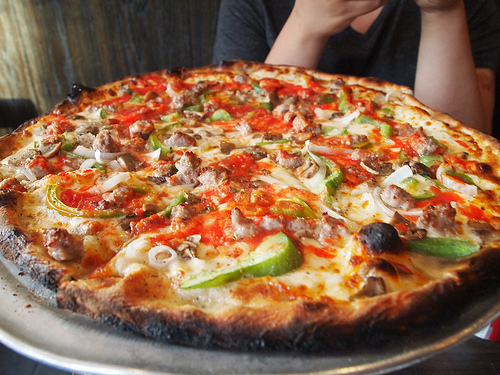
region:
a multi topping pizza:
[1, 59, 498, 349]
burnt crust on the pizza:
[108, 286, 476, 344]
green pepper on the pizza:
[190, 232, 304, 288]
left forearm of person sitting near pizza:
[413, 14, 485, 132]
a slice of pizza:
[56, 151, 462, 337]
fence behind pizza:
[6, 6, 204, 71]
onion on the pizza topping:
[139, 239, 184, 279]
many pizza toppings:
[68, 98, 416, 280]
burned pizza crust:
[2, 225, 499, 349]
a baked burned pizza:
[0, 61, 497, 353]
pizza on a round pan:
[0, 59, 497, 371]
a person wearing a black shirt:
[209, 0, 499, 125]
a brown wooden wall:
[0, 2, 217, 137]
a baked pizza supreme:
[3, 60, 495, 344]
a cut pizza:
[1, 62, 498, 355]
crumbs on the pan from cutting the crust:
[1, 261, 40, 323]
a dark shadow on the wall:
[1, 98, 34, 139]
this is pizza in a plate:
[3, 55, 498, 350]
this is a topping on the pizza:
[190, 222, 326, 282]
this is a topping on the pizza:
[349, 220, 401, 269]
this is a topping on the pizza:
[398, 206, 494, 273]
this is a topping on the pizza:
[41, 170, 143, 236]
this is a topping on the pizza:
[149, 136, 207, 184]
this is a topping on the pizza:
[189, 95, 246, 134]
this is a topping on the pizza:
[284, 139, 346, 203]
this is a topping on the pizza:
[21, 140, 68, 180]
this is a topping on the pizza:
[177, 135, 220, 196]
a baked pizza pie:
[2, 53, 499, 338]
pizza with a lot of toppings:
[12, 48, 499, 370]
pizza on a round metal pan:
[5, 43, 494, 373]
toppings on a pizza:
[85, 91, 269, 247]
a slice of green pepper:
[192, 233, 305, 297]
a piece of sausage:
[90, 128, 120, 155]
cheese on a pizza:
[127, 119, 297, 199]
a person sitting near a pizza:
[205, 31, 497, 126]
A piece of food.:
[348, 222, 390, 257]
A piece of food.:
[396, 232, 478, 260]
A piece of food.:
[378, 187, 422, 215]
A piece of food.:
[317, 155, 344, 200]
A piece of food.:
[251, 132, 294, 147]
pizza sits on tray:
[2, 60, 497, 359]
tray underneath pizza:
[0, 261, 499, 374]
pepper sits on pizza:
[186, 231, 310, 293]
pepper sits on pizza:
[305, 142, 340, 196]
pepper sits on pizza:
[417, 156, 442, 171]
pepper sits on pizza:
[357, 110, 393, 139]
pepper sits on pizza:
[207, 107, 229, 123]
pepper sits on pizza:
[47, 167, 124, 219]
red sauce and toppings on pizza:
[131, 85, 191, 118]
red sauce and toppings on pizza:
[208, 223, 253, 283]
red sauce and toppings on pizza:
[404, 132, 456, 194]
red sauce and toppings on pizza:
[251, 127, 288, 177]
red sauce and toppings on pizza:
[60, 105, 113, 153]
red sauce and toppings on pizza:
[233, 97, 275, 132]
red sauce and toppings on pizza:
[129, 154, 206, 191]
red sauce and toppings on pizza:
[110, 86, 157, 138]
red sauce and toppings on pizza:
[88, 191, 135, 260]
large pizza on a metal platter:
[0, 61, 499, 355]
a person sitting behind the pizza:
[213, 1, 498, 137]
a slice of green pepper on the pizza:
[183, 231, 299, 291]